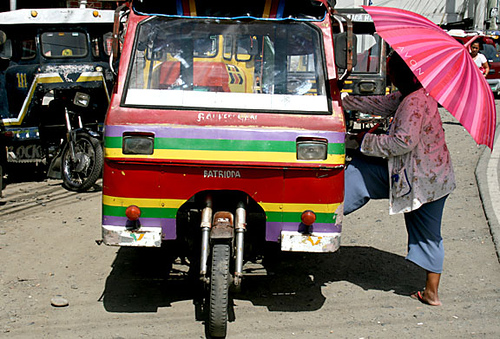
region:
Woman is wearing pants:
[336, 155, 449, 273]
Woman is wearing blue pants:
[339, 148, 451, 275]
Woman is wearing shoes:
[410, 286, 445, 306]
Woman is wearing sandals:
[407, 284, 447, 309]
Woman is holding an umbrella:
[347, 1, 499, 157]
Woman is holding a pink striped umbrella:
[354, 1, 499, 149]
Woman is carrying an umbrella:
[345, 3, 495, 159]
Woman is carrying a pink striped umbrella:
[358, 2, 498, 155]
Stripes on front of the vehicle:
[97, 117, 349, 252]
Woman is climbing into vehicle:
[329, 2, 489, 307]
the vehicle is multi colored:
[107, 8, 350, 257]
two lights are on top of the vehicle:
[29, 10, 104, 18]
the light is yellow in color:
[30, 9, 37, 16]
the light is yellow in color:
[91, 10, 100, 15]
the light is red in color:
[127, 205, 141, 220]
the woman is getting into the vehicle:
[324, 6, 495, 303]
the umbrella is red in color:
[366, 3, 496, 147]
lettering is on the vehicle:
[203, 168, 243, 178]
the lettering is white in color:
[201, 167, 244, 179]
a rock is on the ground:
[49, 295, 66, 307]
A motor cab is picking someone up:
[20, 20, 485, 305]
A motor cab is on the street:
[27, 10, 478, 311]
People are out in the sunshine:
[11, 18, 476, 318]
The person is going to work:
[6, 22, 478, 325]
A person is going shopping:
[36, 21, 481, 306]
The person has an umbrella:
[10, 20, 485, 331]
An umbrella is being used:
[10, 22, 496, 308]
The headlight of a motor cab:
[120, 131, 151, 153]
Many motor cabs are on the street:
[6, 16, 491, 327]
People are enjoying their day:
[5, 16, 498, 323]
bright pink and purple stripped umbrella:
[365, 4, 497, 149]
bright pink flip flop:
[410, 287, 441, 308]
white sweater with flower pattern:
[343, 87, 455, 212]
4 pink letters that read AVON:
[397, 42, 424, 79]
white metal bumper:
[105, 224, 162, 247]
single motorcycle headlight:
[70, 87, 92, 112]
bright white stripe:
[126, 87, 328, 112]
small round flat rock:
[50, 294, 71, 308]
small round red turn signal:
[299, 208, 317, 228]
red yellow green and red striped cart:
[100, 0, 347, 338]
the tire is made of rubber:
[208, 245, 232, 336]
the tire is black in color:
[211, 248, 229, 338]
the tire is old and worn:
[210, 245, 230, 335]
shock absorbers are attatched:
[231, 205, 248, 282]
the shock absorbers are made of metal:
[236, 208, 247, 275]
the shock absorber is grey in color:
[236, 206, 244, 270]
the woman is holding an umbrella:
[353, 2, 497, 304]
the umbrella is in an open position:
[358, 3, 497, 150]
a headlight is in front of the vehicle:
[293, 139, 326, 161]